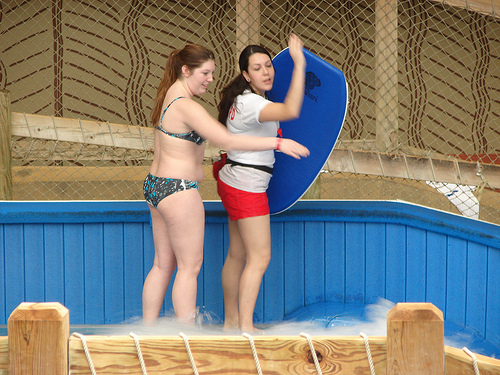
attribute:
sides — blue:
[1, 198, 499, 358]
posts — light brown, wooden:
[319, 274, 471, 364]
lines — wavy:
[111, 1, 155, 127]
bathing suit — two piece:
[139, 95, 203, 208]